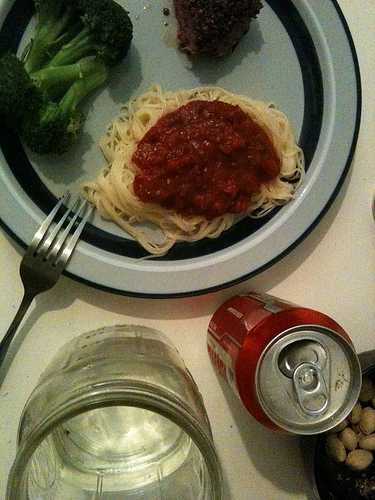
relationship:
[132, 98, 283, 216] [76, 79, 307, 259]
red sauce on spaghetti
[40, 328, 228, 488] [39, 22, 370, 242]
glass on table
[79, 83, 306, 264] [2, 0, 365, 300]
food on plate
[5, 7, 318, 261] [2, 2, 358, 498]
food on table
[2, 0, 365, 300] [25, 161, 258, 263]
plate with rings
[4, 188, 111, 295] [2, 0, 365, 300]
fork on plate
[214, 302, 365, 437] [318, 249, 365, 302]
soda on table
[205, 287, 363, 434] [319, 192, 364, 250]
can on table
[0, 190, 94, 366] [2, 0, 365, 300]
fork resing on plate